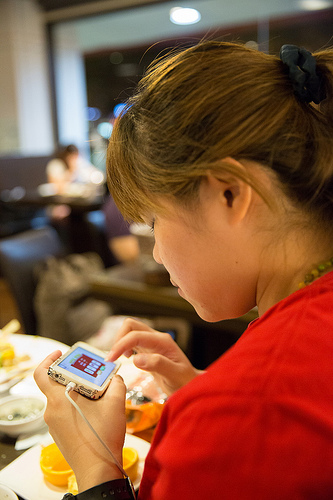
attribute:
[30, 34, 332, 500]
woman — young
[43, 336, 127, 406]
cellphone — white, used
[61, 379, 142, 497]
cord — white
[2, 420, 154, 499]
plate — white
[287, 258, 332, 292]
necklace — beaded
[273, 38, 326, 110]
scrunchie — black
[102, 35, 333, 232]
hair — brown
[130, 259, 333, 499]
shirt — red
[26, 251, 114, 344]
bag — brown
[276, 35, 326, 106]
tie — black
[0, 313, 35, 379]
food — yellow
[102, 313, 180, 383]
fingers — curled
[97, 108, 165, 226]
bangs — straight